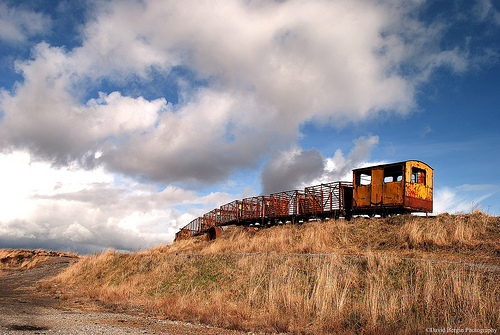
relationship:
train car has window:
[337, 157, 438, 218] [381, 165, 404, 183]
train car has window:
[337, 157, 438, 218] [352, 169, 374, 186]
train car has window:
[337, 157, 438, 218] [411, 166, 429, 189]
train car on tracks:
[337, 157, 438, 218] [412, 212, 498, 220]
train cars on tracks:
[177, 179, 351, 240] [412, 212, 498, 220]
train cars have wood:
[177, 179, 351, 240] [175, 229, 197, 240]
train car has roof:
[337, 157, 438, 218] [353, 157, 440, 176]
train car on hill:
[337, 157, 438, 218] [94, 223, 493, 315]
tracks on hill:
[412, 212, 498, 220] [94, 223, 493, 315]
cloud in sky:
[15, 10, 439, 171] [3, 4, 499, 233]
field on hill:
[71, 216, 496, 334] [94, 223, 493, 315]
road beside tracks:
[1, 255, 224, 333] [412, 212, 498, 220]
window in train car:
[381, 165, 404, 183] [337, 157, 438, 218]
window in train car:
[352, 169, 374, 186] [337, 157, 438, 218]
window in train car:
[411, 166, 429, 189] [337, 157, 438, 218]